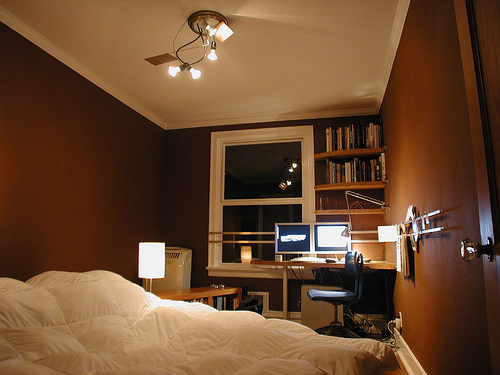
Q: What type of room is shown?
A: It is a bedroom.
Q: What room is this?
A: It is a bedroom.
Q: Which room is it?
A: It is a bedroom.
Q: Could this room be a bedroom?
A: Yes, it is a bedroom.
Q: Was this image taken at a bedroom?
A: Yes, it was taken in a bedroom.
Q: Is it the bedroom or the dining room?
A: It is the bedroom.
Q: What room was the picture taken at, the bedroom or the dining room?
A: It was taken at the bedroom.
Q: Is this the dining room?
A: No, it is the bedroom.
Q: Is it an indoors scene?
A: Yes, it is indoors.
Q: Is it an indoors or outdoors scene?
A: It is indoors.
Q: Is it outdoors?
A: No, it is indoors.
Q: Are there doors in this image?
A: Yes, there is a door.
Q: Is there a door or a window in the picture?
A: Yes, there is a door.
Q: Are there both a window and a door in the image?
A: Yes, there are both a door and a window.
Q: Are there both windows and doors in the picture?
A: Yes, there are both a door and a window.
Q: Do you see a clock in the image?
A: No, there are no clocks.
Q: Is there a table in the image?
A: Yes, there is a table.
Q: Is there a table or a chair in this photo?
A: Yes, there is a table.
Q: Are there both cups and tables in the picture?
A: No, there is a table but no cups.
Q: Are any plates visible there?
A: No, there are no plates.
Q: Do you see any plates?
A: No, there are no plates.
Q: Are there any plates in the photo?
A: No, there are no plates.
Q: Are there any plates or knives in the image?
A: No, there are no plates or knives.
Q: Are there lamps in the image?
A: Yes, there is a lamp.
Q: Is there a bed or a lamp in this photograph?
A: Yes, there is a lamp.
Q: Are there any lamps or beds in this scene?
A: Yes, there is a lamp.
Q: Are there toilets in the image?
A: No, there are no toilets.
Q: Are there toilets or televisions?
A: No, there are no toilets or televisions.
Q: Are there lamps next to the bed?
A: Yes, there is a lamp next to the bed.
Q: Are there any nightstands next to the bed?
A: No, there is a lamp next to the bed.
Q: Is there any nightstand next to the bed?
A: No, there is a lamp next to the bed.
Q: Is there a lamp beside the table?
A: Yes, there is a lamp beside the table.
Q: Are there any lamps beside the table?
A: Yes, there is a lamp beside the table.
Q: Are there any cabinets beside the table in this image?
A: No, there is a lamp beside the table.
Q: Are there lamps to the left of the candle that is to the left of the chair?
A: Yes, there is a lamp to the left of the candle.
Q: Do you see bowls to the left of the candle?
A: No, there is a lamp to the left of the candle.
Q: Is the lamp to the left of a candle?
A: Yes, the lamp is to the left of a candle.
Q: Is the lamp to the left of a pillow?
A: No, the lamp is to the left of a candle.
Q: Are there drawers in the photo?
A: No, there are no drawers.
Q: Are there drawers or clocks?
A: No, there are no drawers or clocks.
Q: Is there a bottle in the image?
A: No, there are no bottles.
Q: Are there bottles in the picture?
A: No, there are no bottles.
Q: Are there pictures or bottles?
A: No, there are no bottles or pictures.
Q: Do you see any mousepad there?
A: No, there are no mouse pads.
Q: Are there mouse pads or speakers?
A: No, there are no mouse pads or speakers.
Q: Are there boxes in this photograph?
A: No, there are no boxes.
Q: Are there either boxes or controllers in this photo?
A: No, there are no boxes or controllers.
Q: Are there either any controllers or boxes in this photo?
A: No, there are no boxes or controllers.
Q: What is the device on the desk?
A: The device is a monitor.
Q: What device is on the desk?
A: The device is a monitor.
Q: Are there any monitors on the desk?
A: Yes, there is a monitor on the desk.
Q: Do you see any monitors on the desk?
A: Yes, there is a monitor on the desk.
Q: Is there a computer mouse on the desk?
A: No, there is a monitor on the desk.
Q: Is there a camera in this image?
A: No, there are no cameras.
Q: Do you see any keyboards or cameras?
A: No, there are no cameras or keyboards.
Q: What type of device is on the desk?
A: The device is a monitor.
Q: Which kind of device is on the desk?
A: The device is a monitor.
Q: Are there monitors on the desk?
A: Yes, there is a monitor on the desk.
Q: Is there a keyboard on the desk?
A: No, there is a monitor on the desk.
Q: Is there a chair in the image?
A: Yes, there is a chair.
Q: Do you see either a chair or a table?
A: Yes, there is a chair.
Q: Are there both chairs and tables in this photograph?
A: Yes, there are both a chair and a table.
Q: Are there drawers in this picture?
A: No, there are no drawers.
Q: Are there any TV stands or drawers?
A: No, there are no drawers or TV stands.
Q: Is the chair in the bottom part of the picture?
A: Yes, the chair is in the bottom of the image.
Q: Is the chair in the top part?
A: No, the chair is in the bottom of the image.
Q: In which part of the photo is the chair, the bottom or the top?
A: The chair is in the bottom of the image.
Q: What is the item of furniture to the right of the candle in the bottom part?
A: The piece of furniture is a chair.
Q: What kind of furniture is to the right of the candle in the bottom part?
A: The piece of furniture is a chair.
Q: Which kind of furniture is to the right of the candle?
A: The piece of furniture is a chair.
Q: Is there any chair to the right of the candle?
A: Yes, there is a chair to the right of the candle.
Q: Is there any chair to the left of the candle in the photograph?
A: No, the chair is to the right of the candle.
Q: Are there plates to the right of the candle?
A: No, there is a chair to the right of the candle.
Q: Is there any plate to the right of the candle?
A: No, there is a chair to the right of the candle.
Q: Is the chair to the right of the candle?
A: Yes, the chair is to the right of the candle.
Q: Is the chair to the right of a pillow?
A: No, the chair is to the right of the candle.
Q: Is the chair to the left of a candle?
A: No, the chair is to the right of a candle.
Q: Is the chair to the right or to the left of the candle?
A: The chair is to the right of the candle.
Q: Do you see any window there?
A: Yes, there is a window.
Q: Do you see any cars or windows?
A: Yes, there is a window.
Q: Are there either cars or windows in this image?
A: Yes, there is a window.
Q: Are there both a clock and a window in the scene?
A: No, there is a window but no clocks.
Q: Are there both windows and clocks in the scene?
A: No, there is a window but no clocks.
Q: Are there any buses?
A: No, there are no buses.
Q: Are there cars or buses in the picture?
A: No, there are no buses or cars.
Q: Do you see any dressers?
A: No, there are no dressers.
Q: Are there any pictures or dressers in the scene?
A: No, there are no dressers or pictures.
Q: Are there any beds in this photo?
A: Yes, there is a bed.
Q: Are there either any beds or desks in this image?
A: Yes, there is a bed.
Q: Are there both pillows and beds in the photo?
A: No, there is a bed but no pillows.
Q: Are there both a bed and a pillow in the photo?
A: No, there is a bed but no pillows.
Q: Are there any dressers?
A: No, there are no dressers.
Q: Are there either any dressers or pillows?
A: No, there are no dressers or pillows.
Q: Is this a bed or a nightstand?
A: This is a bed.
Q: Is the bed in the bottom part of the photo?
A: Yes, the bed is in the bottom of the image.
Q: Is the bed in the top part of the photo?
A: No, the bed is in the bottom of the image.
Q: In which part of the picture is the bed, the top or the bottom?
A: The bed is in the bottom of the image.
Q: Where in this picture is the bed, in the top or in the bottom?
A: The bed is in the bottom of the image.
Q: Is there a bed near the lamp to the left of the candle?
A: Yes, there is a bed near the lamp.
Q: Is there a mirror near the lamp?
A: No, there is a bed near the lamp.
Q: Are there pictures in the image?
A: No, there are no pictures.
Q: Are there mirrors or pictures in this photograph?
A: No, there are no pictures or mirrors.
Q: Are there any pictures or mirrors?
A: No, there are no pictures or mirrors.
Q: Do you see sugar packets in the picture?
A: No, there are no sugar packets.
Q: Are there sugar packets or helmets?
A: No, there are no sugar packets or helmets.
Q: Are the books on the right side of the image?
A: Yes, the books are on the right of the image.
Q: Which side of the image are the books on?
A: The books are on the right of the image.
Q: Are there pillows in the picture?
A: No, there are no pillows.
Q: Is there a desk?
A: Yes, there is a desk.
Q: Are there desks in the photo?
A: Yes, there is a desk.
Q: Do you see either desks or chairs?
A: Yes, there is a desk.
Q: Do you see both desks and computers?
A: Yes, there are both a desk and a computer.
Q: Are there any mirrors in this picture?
A: No, there are no mirrors.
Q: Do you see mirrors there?
A: No, there are no mirrors.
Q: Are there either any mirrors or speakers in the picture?
A: No, there are no mirrors or speakers.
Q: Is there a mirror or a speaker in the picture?
A: No, there are no mirrors or speakers.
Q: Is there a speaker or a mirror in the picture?
A: No, there are no mirrors or speakers.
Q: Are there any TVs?
A: No, there are no tvs.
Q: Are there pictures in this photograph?
A: No, there are no pictures.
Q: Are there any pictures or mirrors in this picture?
A: No, there are no pictures or mirrors.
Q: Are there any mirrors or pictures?
A: No, there are no pictures or mirrors.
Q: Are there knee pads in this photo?
A: No, there are no knee pads.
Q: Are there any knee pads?
A: No, there are no knee pads.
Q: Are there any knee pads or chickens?
A: No, there are no knee pads or chickens.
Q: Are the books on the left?
A: No, the books are on the right of the image.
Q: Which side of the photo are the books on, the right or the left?
A: The books are on the right of the image.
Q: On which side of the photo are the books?
A: The books are on the right of the image.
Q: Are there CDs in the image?
A: No, there are no cds.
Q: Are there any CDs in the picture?
A: No, there are no cds.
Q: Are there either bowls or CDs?
A: No, there are no CDs or bowls.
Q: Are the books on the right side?
A: Yes, the books are on the right of the image.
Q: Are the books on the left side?
A: No, the books are on the right of the image.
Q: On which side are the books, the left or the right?
A: The books are on the right of the image.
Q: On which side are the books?
A: The books are on the right of the image.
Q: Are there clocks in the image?
A: No, there are no clocks.